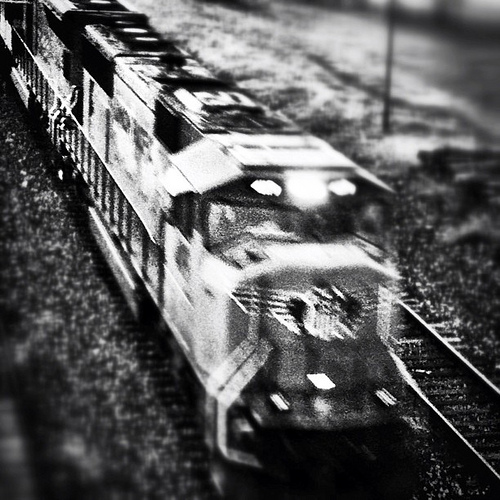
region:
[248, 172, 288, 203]
the headlight of a train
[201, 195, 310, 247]
the windshield of a train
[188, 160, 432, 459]
the front of a train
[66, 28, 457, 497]
a train engine on the tracks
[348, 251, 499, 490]
a pair of train tracks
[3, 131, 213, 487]
gravel next to the train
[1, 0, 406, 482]
a train on the tracks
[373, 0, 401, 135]
a pole by the train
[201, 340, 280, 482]
a bar on the engine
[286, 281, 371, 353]
a logo on the engine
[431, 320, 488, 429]
the rail is black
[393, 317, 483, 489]
the rail is black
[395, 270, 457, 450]
the rail is black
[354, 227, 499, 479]
empty rail road track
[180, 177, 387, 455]
running train on tracks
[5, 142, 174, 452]
gravel on side of tracks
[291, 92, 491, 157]
gravel on side of tracks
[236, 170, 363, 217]
lights on running train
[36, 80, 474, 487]
train running on rail road tracks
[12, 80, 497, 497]
train eunning through gravel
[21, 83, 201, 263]
side of running train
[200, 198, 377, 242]
see through window on train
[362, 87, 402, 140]
single post on side tracks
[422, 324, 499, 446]
A railroad track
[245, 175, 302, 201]
A train light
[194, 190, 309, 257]
A train engineer's wind shield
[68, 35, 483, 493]
A moving train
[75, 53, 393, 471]
This picture contains a lot of noise on the surface.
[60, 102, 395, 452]
This photo is in black and white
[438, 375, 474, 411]
Wood planks making up part of the rail track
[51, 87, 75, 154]
Metal bars to climb into the train.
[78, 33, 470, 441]
Train engine.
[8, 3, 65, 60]
Train car.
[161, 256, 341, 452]
the train is blurry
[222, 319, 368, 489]
the train is blurry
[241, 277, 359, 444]
the train is blurry